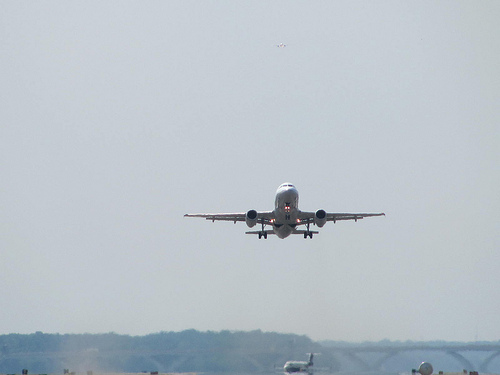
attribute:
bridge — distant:
[319, 337, 497, 374]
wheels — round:
[253, 226, 310, 248]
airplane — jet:
[159, 141, 438, 299]